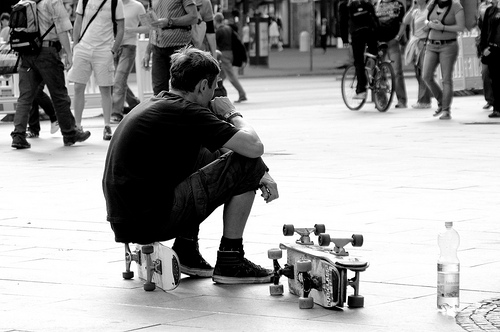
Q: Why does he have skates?
A: Skater.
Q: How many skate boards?
A: 3.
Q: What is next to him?
A: Water bottle.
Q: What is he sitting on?
A: Skateboard.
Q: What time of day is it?
A: Daytime.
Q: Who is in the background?
A: People.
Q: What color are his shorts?
A: Black.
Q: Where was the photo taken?
A: On the streets of the city.